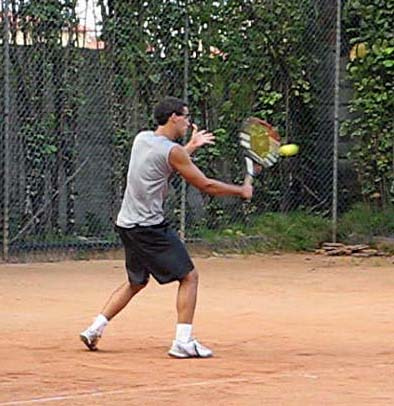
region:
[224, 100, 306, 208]
black and white tennis racket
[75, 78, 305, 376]
man playing tennis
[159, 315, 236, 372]
black and white tennis shoes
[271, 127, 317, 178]
yellow tennis ball in the air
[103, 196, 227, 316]
black tennis shorts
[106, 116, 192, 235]
grey sleeveless shirt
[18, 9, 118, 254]
trees with green leaves and brown bark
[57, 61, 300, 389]
man wearing tennis outfit and playing tennis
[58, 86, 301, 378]
man wearing sleeveless grey shirt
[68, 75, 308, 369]
man wearing black shorts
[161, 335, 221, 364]
white shoe on a foot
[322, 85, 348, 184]
pole of a chain length fence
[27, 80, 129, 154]
tree trunks through a chain length fence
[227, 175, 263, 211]
hand holding a tennis racket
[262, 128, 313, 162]
yellow tennis ball moving through the air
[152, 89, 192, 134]
the head of a man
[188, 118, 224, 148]
a hand wide open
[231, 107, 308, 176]
a tennis racket and a tennis ball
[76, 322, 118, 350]
a white shoe on a foot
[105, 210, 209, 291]
a pair of shorts on a person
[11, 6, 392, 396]
Picture is taken outside.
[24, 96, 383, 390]
Picture is taken during the day.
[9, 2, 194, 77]
The sky is light blue.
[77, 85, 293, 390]
A man is playing tennis.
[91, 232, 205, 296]
The man is wearing shorts.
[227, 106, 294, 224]
The man is holding a tennis racket.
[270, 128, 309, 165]
The tennis ball is yellow.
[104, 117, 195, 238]
The man's shirt is grey in color.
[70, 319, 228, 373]
The man's socks are white.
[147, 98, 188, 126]
The man's hair is black in color.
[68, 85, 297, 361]
A man playing tennis.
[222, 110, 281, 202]
Man holding black, white and red tennis racket.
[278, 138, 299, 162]
A yellow tennis ball in air.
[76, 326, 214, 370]
Man wearing white and gray tennis shoes.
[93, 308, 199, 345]
Man wearing white socks.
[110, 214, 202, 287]
Man dressed in dark gray shorts.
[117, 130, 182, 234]
Man dressed in short sleeve t-shirt.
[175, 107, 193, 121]
Man wearing eyeglasses over eyes.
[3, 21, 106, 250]
Chain link fence around tennis court.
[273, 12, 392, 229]
Trees growing behind chain link fence.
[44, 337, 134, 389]
red clay on tennis court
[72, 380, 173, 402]
white lines on red clay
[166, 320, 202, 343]
ankle length white socks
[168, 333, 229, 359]
black markings on white sneakers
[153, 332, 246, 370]
white sneakers on man's feet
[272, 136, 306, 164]
yellow tennis ball in the air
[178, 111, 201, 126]
glasses on man's face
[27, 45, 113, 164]
long chain link fence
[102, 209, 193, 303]
man wearing black shorts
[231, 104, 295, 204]
white and black and red tennis racket